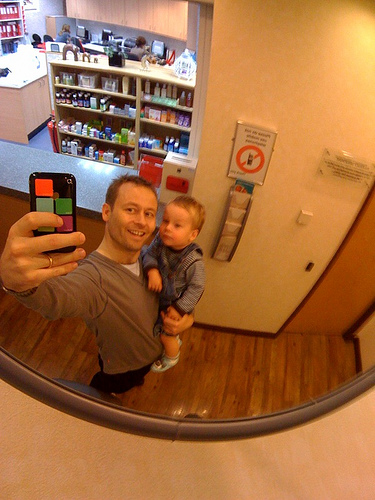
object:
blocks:
[34, 178, 72, 233]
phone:
[28, 171, 77, 256]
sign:
[226, 119, 276, 184]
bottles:
[53, 87, 91, 111]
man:
[1, 173, 204, 399]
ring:
[46, 255, 53, 268]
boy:
[141, 195, 205, 371]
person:
[56, 24, 71, 45]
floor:
[2, 329, 375, 421]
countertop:
[0, 141, 178, 232]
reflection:
[0, 0, 375, 437]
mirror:
[0, 0, 375, 500]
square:
[35, 178, 53, 197]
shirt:
[2, 249, 168, 373]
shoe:
[151, 351, 181, 372]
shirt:
[140, 241, 205, 314]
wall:
[197, 0, 375, 337]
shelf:
[45, 14, 196, 173]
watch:
[0, 283, 39, 298]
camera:
[67, 178, 72, 184]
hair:
[170, 193, 205, 231]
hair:
[104, 174, 158, 208]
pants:
[90, 363, 153, 395]